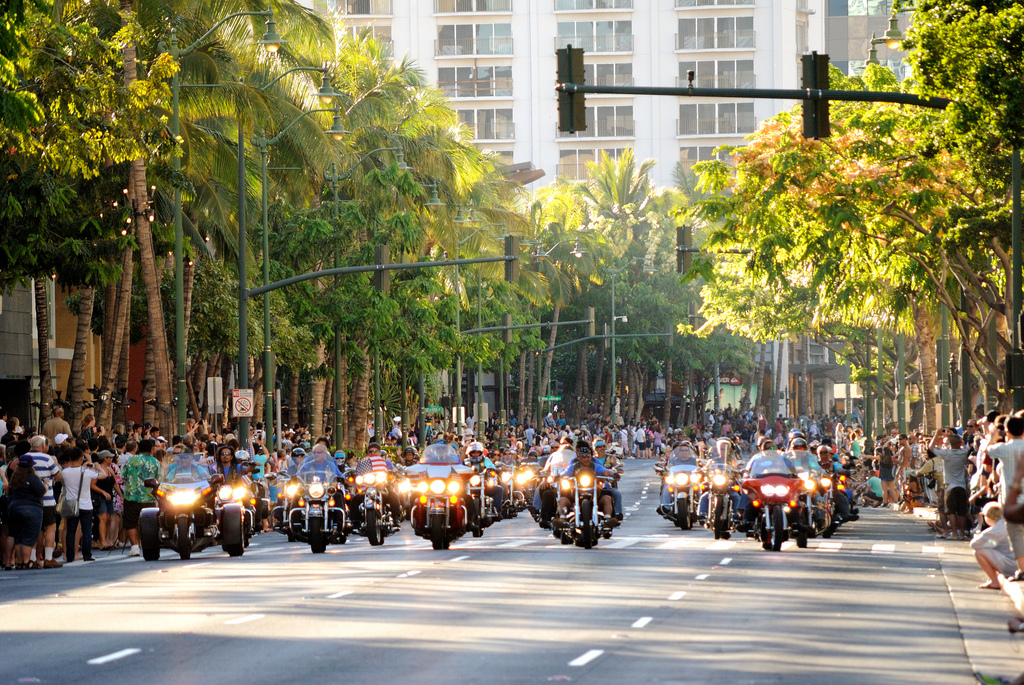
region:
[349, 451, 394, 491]
American flag in between the bikes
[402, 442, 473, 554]
bike with three headlights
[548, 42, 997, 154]
closest traffic signal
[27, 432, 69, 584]
spectator in white and blue striped shirt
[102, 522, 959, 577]
crosswalk the bikers are going over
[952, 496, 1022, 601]
person sitting on the curb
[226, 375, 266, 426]
no sign on the light post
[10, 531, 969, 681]
section on road the bikers are about to drive on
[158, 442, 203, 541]
person riding in group on bike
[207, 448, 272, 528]
person riding in group on bike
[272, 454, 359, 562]
person riding in group on bike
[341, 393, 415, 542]
person riding in group on bike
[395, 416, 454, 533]
person riding in group on bike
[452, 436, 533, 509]
person riding in group on bike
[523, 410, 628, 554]
person riding in group on bike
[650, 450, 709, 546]
person riding in group on bike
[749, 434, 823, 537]
person riding in group on bike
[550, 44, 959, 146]
traffic lights suspended on a black metal pole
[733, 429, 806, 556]
motorcycle with its headlights on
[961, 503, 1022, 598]
a person is crouched on the sidewalk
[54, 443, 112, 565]
man is taking a photograph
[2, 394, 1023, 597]
a crowd of people watch motorcycles ride past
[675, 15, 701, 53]
window in a high rise building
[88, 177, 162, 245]
small lights on a palm tree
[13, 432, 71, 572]
man with grey hair wearing a striped shirt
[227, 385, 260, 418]
sign on a tall green metal post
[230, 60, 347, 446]
street lamp is on a green post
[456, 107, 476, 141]
window facing street full of motorcycles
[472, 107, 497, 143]
window facing street full of motorcycles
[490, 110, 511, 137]
window facing street full of motorcycles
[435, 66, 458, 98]
window facing street full of motorcycles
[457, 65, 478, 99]
window facing street full of motorcycles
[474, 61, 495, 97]
window facing street full of motorcycles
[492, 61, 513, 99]
window facing street full of motorcycles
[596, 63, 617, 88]
window facing street full of motorcycles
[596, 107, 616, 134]
window facing street full of motorcycles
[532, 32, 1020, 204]
Two traffic lights above street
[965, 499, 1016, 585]
Person sits on sidewalk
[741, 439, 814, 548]
A man rides a red motorcycle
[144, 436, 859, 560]
A group of motorcyclists ride down street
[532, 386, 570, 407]
A green street sign near street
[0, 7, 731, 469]
A row of trees line the road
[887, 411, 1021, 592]
Group of people watch the parade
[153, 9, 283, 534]
A green lamp post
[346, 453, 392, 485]
An American flag on a motorcycle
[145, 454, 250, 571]
a motorcycle on the road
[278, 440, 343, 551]
a motorcycle on the road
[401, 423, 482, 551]
a motorcycle on the road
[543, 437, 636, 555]
a motorcycle on the road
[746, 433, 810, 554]
a motorcycle on the road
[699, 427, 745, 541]
a motorcycle on the road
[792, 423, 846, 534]
a motorcycle on the road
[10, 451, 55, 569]
person on edge of street watching a parade of motorcycles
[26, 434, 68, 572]
person on edge of street watching a parade of motorcycles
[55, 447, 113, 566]
person on edge of street watching a parade of motorcycles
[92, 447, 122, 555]
person on edge of street watching a parade of motorcycles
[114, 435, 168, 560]
person on edge of street watching a parade of motorcycles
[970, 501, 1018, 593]
person on edge of street watching a parade of motorcycles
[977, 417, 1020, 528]
person on edge of street watching a parade of motorcycles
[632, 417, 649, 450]
person on edge of street watching a parade of motorcycles